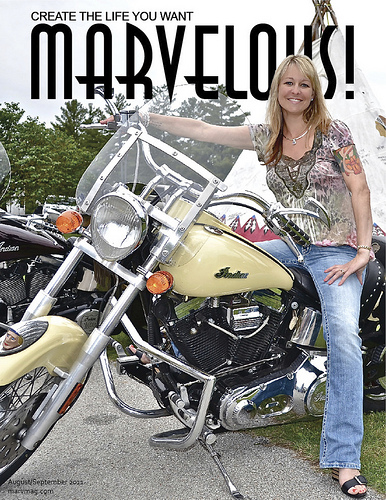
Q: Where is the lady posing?
A: Motorcycle.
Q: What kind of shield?
A: Bug.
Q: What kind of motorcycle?
A: Harley davidson.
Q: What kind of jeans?
A: White washed.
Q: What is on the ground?
A: Gravel.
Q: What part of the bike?
A: Engine.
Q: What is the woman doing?
A: Sitting.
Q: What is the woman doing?
A: Posing.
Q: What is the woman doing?
A: Sitting.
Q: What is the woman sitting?
A: A motorcycle.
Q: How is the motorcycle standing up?
A: Using the kickstand.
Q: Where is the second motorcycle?
A: Behind the first.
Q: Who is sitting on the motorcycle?
A: The blonde woman.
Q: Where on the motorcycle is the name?
A: On the frame.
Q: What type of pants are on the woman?
A: Denim Jeans.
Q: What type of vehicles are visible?
A: Motorcycles.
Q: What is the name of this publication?
A: Marvelous.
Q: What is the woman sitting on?
A: A motorcycle.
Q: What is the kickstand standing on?
A: Asphalt.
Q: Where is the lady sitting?
A: On the bike.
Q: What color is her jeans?
A: They blue.